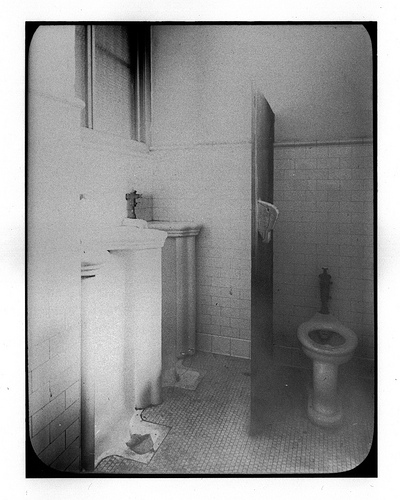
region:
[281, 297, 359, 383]
the toilet seat is down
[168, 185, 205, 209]
the wall is tiled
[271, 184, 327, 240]
the wall is tiled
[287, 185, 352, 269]
the wall is tiled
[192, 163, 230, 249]
the wall is tiled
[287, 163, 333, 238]
the wall is tiled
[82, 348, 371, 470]
tiled bathroom floor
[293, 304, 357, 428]
a white porcelain toilet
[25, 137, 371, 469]
the bottom of the walls are white brick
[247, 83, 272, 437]
wooden privacy divider beside the toilet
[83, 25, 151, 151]
dirty window with blinds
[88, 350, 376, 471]
dirty tiled bathroom floor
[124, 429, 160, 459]
rock laying in the bathroom floor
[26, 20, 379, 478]
black border bordering the image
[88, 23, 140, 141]
closed blinds covering the window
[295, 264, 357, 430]
white dirty toilet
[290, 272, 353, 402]
This is a toilet in a public restroom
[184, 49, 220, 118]
The color of this wall is a bright white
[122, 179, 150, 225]
There is a nozzle made of stainless steel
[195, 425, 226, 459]
The floor of this restroom is dirty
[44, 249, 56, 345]
The walls of this restroom are a bright white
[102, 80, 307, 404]
Jackson Mingus took this photo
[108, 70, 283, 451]
This photo was taken last week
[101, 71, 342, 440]
This photo was purchased by Harland Gray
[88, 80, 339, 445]
The publications available hail this photo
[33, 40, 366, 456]
the picture is black and white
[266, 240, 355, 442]
the toilet doesn`t have a lid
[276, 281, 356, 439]
the toilet is white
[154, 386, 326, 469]
the floor is tiles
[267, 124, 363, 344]
the walls are white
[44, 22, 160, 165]
the window is closed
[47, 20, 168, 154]
the window pane is dark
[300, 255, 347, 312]
a pipe connected to the wall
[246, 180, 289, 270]
a toilet paper dispenser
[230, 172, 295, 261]
the dispenser is white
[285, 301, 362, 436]
a tall white toilet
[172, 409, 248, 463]
dirty tiles on a floor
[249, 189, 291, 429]
a wall divider between the restroom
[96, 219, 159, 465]
toilets on a wall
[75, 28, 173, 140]
a window on the wall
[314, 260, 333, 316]
a metal pipe behind the toilet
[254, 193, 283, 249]
a hand towel on the wall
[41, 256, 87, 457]
white tiles on the wall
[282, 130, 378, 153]
the wall edge of tile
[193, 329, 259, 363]
a tile basboard